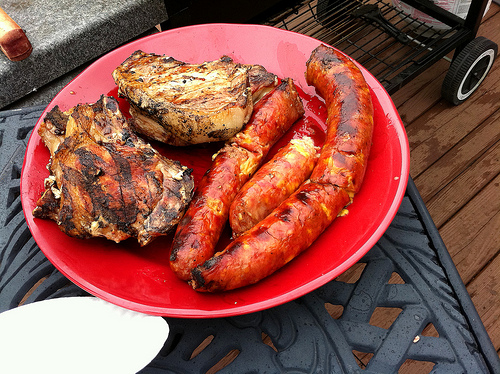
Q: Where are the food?
A: On the plate.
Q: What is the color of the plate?
A: Red.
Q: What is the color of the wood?
A: Brown.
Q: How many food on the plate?
A: Five.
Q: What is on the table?
A: Food.